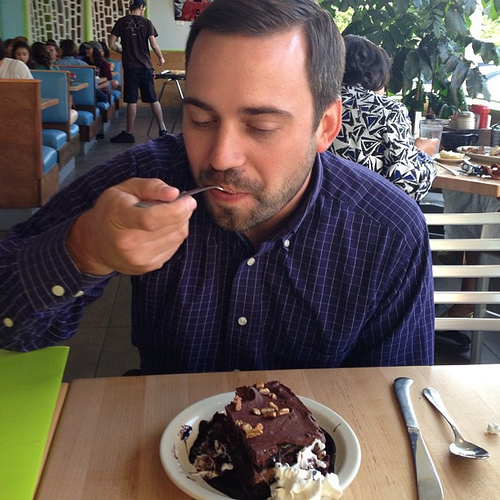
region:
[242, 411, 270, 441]
nuts on the brownie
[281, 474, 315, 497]
whipped cream on the side of plate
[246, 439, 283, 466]
chocolate frosting on the brownie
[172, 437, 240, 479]
brownie in a white dish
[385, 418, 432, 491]
fork next to spoon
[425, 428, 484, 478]
spoon on the table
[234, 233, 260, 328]
buttons on his shirt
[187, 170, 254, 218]
spoon is man's mouth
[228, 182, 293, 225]
man has a beard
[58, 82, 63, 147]
seats are blue in the booths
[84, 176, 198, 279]
the mans right hand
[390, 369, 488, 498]
spoon and knife lying on the table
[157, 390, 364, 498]
white plate holding the food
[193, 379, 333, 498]
yummy chocolate desert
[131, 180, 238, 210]
spoon in the man's mouth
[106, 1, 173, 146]
man wearing black shirt and pants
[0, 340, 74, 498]
green object laying on table next to the man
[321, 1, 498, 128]
green plant behind man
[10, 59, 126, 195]
row of brown and blue chairs and tables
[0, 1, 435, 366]
man wearing a blue checked shirt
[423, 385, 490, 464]
a silver spoon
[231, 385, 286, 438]
nuts on tops of chocolate cake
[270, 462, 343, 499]
whipped cream on bowl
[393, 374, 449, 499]
a silver knife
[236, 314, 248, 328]
a white button on blue shirt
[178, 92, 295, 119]
man has two eyebrows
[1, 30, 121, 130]
other people are dining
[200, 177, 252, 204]
spoon is in man's mouth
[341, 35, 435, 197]
a woman is sitting behind man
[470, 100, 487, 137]
a bottle of ketchup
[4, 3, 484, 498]
the man is eating a chocolate cake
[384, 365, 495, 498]
a knife and a spoon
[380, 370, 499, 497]
utensils used for eating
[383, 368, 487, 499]
eating utensils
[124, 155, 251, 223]
the fork is in his mouth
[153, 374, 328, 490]
a chocolate cake topped with nuts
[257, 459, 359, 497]
whipped cream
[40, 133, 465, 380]
his shirt is navy blue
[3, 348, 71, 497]
a green menu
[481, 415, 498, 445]
a straw wrapper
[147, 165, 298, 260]
man is holding a utensil with his right hand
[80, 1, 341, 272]
man has a silver utensil in his mouth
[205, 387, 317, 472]
chocolate covered dessert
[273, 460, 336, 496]
white whip cream on the side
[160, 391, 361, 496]
circle plate of dessert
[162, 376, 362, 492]
plate of dessert with whip cream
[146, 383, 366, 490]
chocolate dessert with nuts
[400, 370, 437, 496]
silver butter knife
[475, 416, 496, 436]
crumpled piece of white paper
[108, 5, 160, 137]
man standing in the back